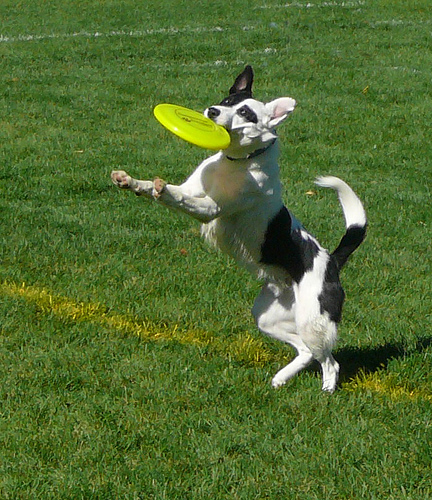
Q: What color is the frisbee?
A: Yellow.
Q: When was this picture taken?
A: Daytime.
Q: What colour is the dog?
A: Black and white.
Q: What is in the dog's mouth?
A: A frisbee.